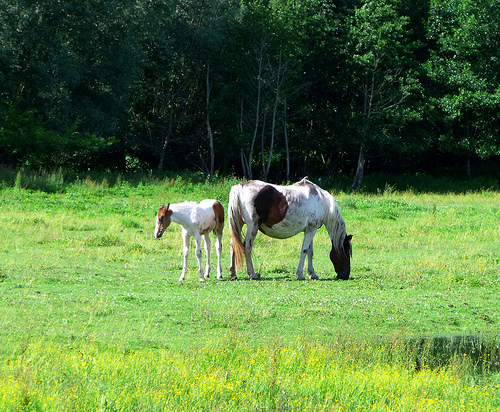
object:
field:
[0, 183, 499, 411]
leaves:
[464, 37, 479, 47]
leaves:
[456, 69, 473, 79]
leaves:
[458, 87, 475, 98]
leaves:
[403, 73, 416, 87]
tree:
[0, 0, 499, 186]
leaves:
[471, 11, 487, 21]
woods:
[0, 0, 499, 196]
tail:
[224, 184, 246, 269]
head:
[151, 200, 173, 240]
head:
[327, 232, 356, 281]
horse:
[225, 175, 353, 282]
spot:
[251, 184, 288, 230]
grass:
[0, 176, 499, 411]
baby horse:
[151, 198, 225, 287]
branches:
[356, 24, 374, 37]